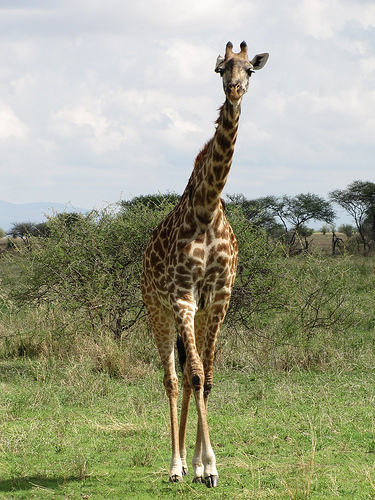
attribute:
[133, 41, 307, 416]
giraffe — tall, yellow, standing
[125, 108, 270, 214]
neck — long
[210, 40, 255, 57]
antlers — small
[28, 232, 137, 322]
trees — sparse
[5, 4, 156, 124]
clouds — white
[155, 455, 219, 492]
hooves — black, dark, grey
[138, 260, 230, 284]
spots — brown, dark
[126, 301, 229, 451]
legs — crossed, skinny, creamy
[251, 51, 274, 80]
ear — folded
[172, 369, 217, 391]
knees — dark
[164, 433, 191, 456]
shins — thin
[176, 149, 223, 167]
mane — brushy